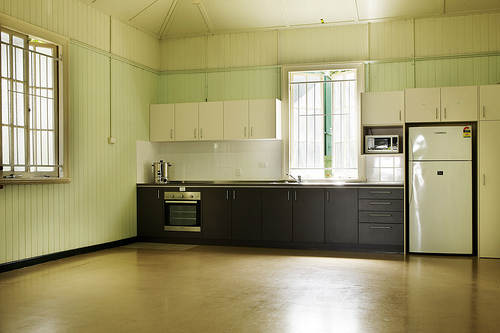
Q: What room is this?
A: Kitchen.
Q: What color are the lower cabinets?
A: Brown/black.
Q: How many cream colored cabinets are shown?
A: 10.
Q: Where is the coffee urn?
A: On top of the counter.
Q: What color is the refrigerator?
A: White.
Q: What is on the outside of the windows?
A: Bars.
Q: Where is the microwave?
A: Next to the refrigerator.